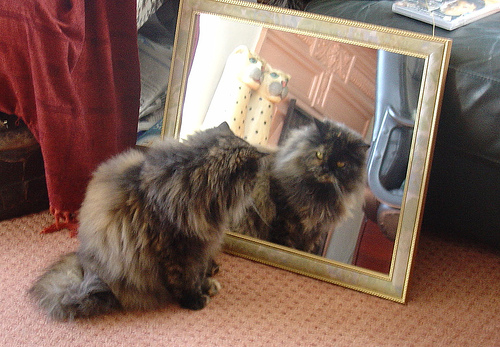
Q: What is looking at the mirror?
A: A fluffy cat is.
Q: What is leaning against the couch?
A: Its a mirror.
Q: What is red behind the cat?
A: It's part of a red curtain or maybe a blanket.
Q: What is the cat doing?
A: The cat is sitting down.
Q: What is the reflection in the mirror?
A: It is the cat that is in front of the mirror.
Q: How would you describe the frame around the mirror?
A: It is a gold frame.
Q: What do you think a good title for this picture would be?
A: A reflection in the mirror.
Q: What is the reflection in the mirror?
A: A cat.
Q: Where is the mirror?
A: Floor leaning the leather sofa.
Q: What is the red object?
A: Blanket.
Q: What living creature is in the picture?
A: Cat.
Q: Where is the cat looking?
A: In the mirror.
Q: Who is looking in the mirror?
A: The cat.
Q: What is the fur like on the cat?
A: Very fluffy.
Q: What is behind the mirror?
A: The bed.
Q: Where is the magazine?
A: On the bed.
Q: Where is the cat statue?
A: Next to the hearth.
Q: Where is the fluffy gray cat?
A: Next to the curtain.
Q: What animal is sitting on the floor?
A: Cat.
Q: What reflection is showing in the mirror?
A: Cat.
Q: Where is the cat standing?
A: Front of mirror.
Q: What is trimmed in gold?
A: Mirror.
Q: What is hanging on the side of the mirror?
A: Blanket.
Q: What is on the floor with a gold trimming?
A: Mirror.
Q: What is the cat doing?
A: Staring in the mirror.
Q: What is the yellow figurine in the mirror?
A: Cats.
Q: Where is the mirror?
A: On floor.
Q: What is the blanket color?
A: Burgundy.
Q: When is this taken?
A: During the day.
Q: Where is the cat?
A: In front of the mirror.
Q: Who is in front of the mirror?
A: A cat.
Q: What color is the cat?
A: Gray.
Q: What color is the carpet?
A: Orange.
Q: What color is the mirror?
A: Silver.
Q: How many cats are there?
A: One.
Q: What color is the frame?
A: Gold.